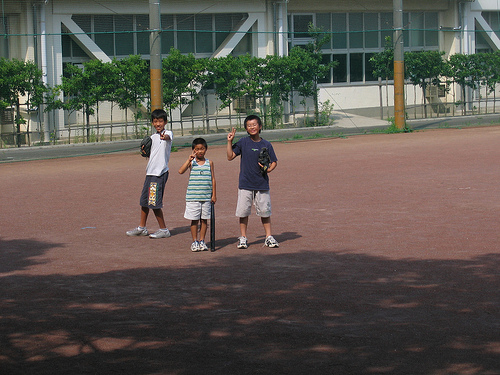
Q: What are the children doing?
A: Posing for a picture.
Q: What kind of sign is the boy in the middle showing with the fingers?
A: Peace.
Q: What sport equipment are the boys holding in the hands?
A: A bat and baseball gloves.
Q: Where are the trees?
A: The trees are behind the fence.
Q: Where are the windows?
A: The windows are on the building.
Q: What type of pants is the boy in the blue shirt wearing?
A: The boy is wearing khaki shorts.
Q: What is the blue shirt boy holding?
A: The boy is holding a baseball glove.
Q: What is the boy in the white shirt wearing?
A: The boy is wearing shorts.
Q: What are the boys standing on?
A: The boys are standing on pavement.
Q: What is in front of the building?
A: A fence is in front of the building.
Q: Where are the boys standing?
A: The boys are standing in front of the building.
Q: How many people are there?
A: Three.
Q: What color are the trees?
A: Green.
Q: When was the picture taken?
A: Daytime.